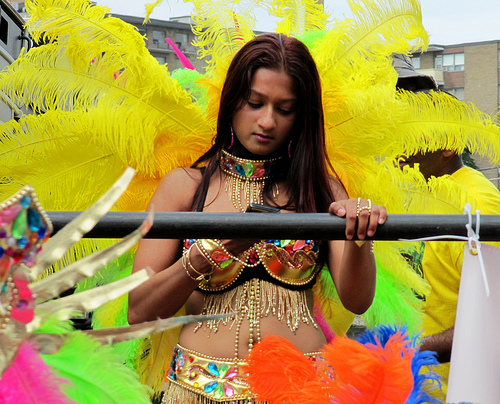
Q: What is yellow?
A: Feathers.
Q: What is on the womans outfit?
A: Jewels.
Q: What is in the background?
A: A building.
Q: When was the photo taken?
A: Daytime.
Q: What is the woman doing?
A: Texting.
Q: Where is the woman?
A: At a performance.